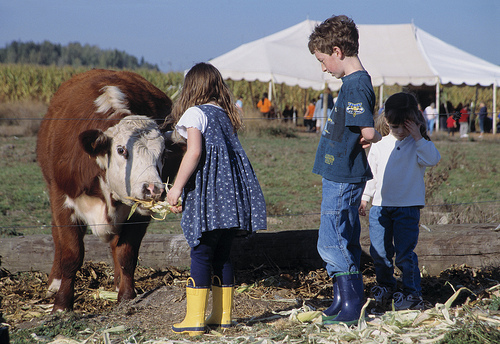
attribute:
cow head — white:
[78, 113, 173, 215]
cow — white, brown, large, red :
[32, 66, 174, 307]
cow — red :
[36, 68, 173, 335]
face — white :
[94, 107, 164, 206]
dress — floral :
[178, 101, 296, 248]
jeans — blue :
[363, 203, 425, 300]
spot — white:
[92, 85, 132, 116]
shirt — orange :
[256, 95, 272, 112]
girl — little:
[162, 62, 254, 332]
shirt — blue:
[317, 67, 375, 186]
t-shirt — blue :
[309, 68, 378, 183]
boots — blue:
[305, 265, 372, 330]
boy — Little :
[359, 91, 440, 306]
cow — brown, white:
[41, 67, 184, 305]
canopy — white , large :
[169, 22, 499, 135]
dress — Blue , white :
[177, 105, 267, 248]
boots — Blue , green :
[319, 269, 366, 326]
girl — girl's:
[141, 44, 288, 322]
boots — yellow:
[168, 280, 272, 338]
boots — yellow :
[173, 277, 233, 336]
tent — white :
[178, 15, 499, 125]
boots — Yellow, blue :
[162, 287, 235, 341]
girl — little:
[154, 53, 272, 341]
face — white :
[105, 114, 173, 208]